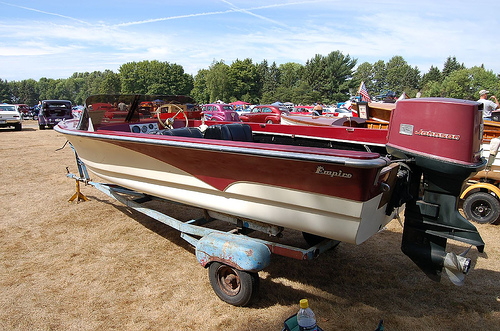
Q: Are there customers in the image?
A: No, there are no customers.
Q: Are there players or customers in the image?
A: No, there are no customers or players.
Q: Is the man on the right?
A: Yes, the man is on the right of the image.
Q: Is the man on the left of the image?
A: No, the man is on the right of the image.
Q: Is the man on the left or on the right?
A: The man is on the right of the image.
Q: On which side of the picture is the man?
A: The man is on the right of the image.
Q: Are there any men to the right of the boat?
A: Yes, there is a man to the right of the boat.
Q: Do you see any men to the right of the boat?
A: Yes, there is a man to the right of the boat.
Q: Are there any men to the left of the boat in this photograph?
A: No, the man is to the right of the boat.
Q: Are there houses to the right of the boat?
A: No, there is a man to the right of the boat.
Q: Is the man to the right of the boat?
A: Yes, the man is to the right of the boat.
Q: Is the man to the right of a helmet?
A: No, the man is to the right of the boat.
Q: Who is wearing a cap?
A: The man is wearing a cap.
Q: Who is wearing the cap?
A: The man is wearing a cap.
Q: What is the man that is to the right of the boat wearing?
A: The man is wearing a cap.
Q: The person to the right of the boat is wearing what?
A: The man is wearing a cap.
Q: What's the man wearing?
A: The man is wearing a cap.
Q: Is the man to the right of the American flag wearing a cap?
A: Yes, the man is wearing a cap.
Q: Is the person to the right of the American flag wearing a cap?
A: Yes, the man is wearing a cap.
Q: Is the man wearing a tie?
A: No, the man is wearing a cap.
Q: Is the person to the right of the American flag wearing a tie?
A: No, the man is wearing a cap.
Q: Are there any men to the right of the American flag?
A: Yes, there is a man to the right of the American flag.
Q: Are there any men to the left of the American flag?
A: No, the man is to the right of the American flag.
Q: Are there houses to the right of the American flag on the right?
A: No, there is a man to the right of the American flag.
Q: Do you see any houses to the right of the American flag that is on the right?
A: No, there is a man to the right of the American flag.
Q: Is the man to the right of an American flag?
A: Yes, the man is to the right of an American flag.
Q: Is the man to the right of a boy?
A: No, the man is to the right of an American flag.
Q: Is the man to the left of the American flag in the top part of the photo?
A: No, the man is to the right of the American flag.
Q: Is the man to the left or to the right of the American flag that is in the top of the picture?
A: The man is to the right of the American flag.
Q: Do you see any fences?
A: No, there are no fences.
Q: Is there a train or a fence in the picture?
A: No, there are no fences or trains.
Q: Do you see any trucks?
A: No, there are no trucks.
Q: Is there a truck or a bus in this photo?
A: No, there are no trucks or buses.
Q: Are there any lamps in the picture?
A: No, there are no lamps.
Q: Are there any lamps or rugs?
A: No, there are no lamps or rugs.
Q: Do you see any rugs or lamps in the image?
A: No, there are no lamps or rugs.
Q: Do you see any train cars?
A: No, there are no train cars.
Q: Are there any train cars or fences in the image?
A: No, there are no train cars or fences.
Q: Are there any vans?
A: No, there are no vans.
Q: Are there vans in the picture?
A: No, there are no vans.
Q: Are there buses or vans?
A: No, there are no vans or buses.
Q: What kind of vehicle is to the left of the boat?
A: The vehicle is a car.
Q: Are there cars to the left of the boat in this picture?
A: Yes, there is a car to the left of the boat.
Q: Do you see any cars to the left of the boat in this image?
A: Yes, there is a car to the left of the boat.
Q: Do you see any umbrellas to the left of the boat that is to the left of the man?
A: No, there is a car to the left of the boat.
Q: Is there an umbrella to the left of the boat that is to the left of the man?
A: No, there is a car to the left of the boat.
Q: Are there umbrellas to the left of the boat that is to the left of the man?
A: No, there is a car to the left of the boat.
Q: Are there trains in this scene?
A: No, there are no trains.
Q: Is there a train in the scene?
A: No, there are no trains.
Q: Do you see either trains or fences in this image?
A: No, there are no trains or fences.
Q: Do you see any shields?
A: No, there are no shields.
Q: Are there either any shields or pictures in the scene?
A: No, there are no shields or pictures.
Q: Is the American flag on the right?
A: Yes, the American flag is on the right of the image.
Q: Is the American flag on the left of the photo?
A: No, the American flag is on the right of the image.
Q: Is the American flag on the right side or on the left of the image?
A: The American flag is on the right of the image.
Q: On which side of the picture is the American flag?
A: The American flag is on the right of the image.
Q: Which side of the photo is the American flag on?
A: The American flag is on the right of the image.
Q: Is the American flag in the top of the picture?
A: Yes, the American flag is in the top of the image.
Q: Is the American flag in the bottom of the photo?
A: No, the American flag is in the top of the image.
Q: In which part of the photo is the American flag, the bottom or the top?
A: The American flag is in the top of the image.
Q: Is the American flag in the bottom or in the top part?
A: The American flag is in the top of the image.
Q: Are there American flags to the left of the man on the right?
A: Yes, there is an American flag to the left of the man.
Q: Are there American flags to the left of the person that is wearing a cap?
A: Yes, there is an American flag to the left of the man.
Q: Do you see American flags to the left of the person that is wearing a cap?
A: Yes, there is an American flag to the left of the man.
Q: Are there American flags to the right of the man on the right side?
A: No, the American flag is to the left of the man.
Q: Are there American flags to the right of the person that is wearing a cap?
A: No, the American flag is to the left of the man.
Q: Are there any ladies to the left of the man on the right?
A: No, there is an American flag to the left of the man.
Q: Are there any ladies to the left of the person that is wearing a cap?
A: No, there is an American flag to the left of the man.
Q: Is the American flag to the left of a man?
A: Yes, the American flag is to the left of a man.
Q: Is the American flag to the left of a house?
A: No, the American flag is to the left of a man.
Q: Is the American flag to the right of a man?
A: No, the American flag is to the left of a man.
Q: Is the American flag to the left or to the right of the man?
A: The American flag is to the left of the man.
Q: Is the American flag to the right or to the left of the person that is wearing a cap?
A: The American flag is to the left of the man.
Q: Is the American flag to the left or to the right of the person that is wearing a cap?
A: The American flag is to the left of the man.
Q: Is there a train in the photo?
A: No, there are no trains.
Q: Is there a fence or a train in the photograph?
A: No, there are no trains or fences.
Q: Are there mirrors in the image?
A: No, there are no mirrors.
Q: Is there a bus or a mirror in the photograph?
A: No, there are no mirrors or buses.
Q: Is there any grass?
A: Yes, there is grass.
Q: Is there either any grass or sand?
A: Yes, there is grass.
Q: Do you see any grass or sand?
A: Yes, there is grass.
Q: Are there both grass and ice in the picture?
A: No, there is grass but no ice.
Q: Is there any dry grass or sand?
A: Yes, there is dry grass.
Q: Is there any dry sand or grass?
A: Yes, there is dry grass.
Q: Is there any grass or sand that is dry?
A: Yes, the grass is dry.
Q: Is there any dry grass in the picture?
A: Yes, there is dry grass.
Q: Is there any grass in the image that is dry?
A: Yes, there is grass that is dry.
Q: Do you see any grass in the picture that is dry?
A: Yes, there is grass that is dry.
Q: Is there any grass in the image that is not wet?
A: Yes, there is dry grass.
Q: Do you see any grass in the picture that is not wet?
A: Yes, there is dry grass.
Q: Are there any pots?
A: No, there are no pots.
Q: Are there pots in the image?
A: No, there are no pots.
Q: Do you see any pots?
A: No, there are no pots.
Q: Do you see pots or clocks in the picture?
A: No, there are no pots or clocks.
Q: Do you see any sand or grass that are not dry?
A: No, there is grass but it is dry.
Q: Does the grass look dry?
A: Yes, the grass is dry.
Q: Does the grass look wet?
A: No, the grass is dry.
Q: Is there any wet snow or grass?
A: No, there is grass but it is dry.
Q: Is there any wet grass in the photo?
A: No, there is grass but it is dry.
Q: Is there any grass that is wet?
A: No, there is grass but it is dry.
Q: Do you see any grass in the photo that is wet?
A: No, there is grass but it is dry.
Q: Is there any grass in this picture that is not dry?
A: No, there is grass but it is dry.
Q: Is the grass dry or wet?
A: The grass is dry.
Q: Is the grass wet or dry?
A: The grass is dry.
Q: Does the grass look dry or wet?
A: The grass is dry.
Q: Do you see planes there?
A: No, there are no planes.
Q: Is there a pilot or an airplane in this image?
A: No, there are no airplanes or pilots.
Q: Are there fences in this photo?
A: No, there are no fences.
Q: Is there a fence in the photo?
A: No, there are no fences.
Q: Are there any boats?
A: Yes, there is a boat.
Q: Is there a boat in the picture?
A: Yes, there is a boat.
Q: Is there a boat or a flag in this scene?
A: Yes, there is a boat.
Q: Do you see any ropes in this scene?
A: No, there are no ropes.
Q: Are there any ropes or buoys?
A: No, there are no ropes or buoys.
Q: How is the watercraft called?
A: The watercraft is a boat.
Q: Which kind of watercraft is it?
A: The watercraft is a boat.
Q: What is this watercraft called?
A: This is a boat.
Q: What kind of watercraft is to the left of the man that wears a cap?
A: The watercraft is a boat.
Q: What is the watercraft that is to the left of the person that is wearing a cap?
A: The watercraft is a boat.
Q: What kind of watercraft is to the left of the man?
A: The watercraft is a boat.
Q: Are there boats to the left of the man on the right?
A: Yes, there is a boat to the left of the man.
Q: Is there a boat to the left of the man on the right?
A: Yes, there is a boat to the left of the man.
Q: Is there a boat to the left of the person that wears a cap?
A: Yes, there is a boat to the left of the man.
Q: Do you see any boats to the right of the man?
A: No, the boat is to the left of the man.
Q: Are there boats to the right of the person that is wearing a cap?
A: No, the boat is to the left of the man.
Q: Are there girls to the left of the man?
A: No, there is a boat to the left of the man.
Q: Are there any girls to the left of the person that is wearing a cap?
A: No, there is a boat to the left of the man.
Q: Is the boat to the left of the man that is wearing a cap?
A: Yes, the boat is to the left of the man.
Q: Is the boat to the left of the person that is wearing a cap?
A: Yes, the boat is to the left of the man.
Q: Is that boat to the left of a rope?
A: No, the boat is to the left of the man.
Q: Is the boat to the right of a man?
A: No, the boat is to the left of a man.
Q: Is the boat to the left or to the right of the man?
A: The boat is to the left of the man.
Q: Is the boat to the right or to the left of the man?
A: The boat is to the left of the man.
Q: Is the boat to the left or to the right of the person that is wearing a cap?
A: The boat is to the left of the man.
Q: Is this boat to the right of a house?
A: No, the boat is to the right of a car.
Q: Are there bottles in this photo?
A: Yes, there is a bottle.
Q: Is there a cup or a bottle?
A: Yes, there is a bottle.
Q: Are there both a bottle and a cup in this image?
A: No, there is a bottle but no cups.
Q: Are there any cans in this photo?
A: No, there are no cans.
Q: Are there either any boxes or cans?
A: No, there are no cans or boxes.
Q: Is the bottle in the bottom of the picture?
A: Yes, the bottle is in the bottom of the image.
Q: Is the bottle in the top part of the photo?
A: No, the bottle is in the bottom of the image.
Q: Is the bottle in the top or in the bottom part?
A: The bottle is in the bottom of the image.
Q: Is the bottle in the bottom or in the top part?
A: The bottle is in the bottom of the image.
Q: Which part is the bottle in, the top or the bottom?
A: The bottle is in the bottom of the image.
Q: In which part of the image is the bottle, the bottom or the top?
A: The bottle is in the bottom of the image.